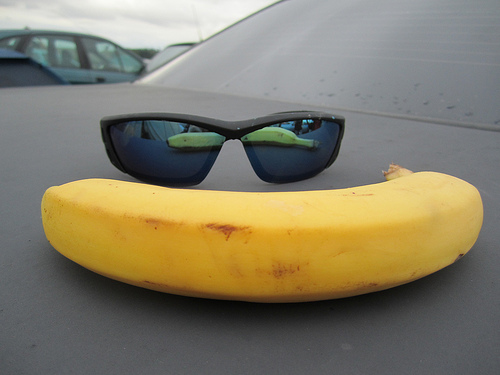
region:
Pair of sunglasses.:
[99, 85, 375, 182]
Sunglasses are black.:
[67, 95, 375, 182]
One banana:
[39, 151, 469, 373]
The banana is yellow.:
[44, 177, 487, 308]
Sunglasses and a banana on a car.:
[47, 92, 484, 313]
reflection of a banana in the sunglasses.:
[165, 122, 333, 152]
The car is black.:
[22, 77, 478, 365]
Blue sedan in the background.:
[2, 18, 153, 95]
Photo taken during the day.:
[27, 2, 496, 369]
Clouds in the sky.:
[6, 3, 264, 54]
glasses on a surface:
[98, 66, 363, 185]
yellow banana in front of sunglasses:
[57, 161, 474, 320]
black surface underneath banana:
[264, 304, 375, 350]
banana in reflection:
[273, 122, 313, 160]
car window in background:
[71, 21, 140, 75]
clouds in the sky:
[141, 9, 186, 38]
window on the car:
[30, 34, 76, 78]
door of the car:
[91, 78, 113, 88]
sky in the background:
[139, 11, 196, 32]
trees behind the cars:
[138, 38, 159, 63]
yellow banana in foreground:
[37, 161, 489, 308]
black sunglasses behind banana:
[91, 90, 348, 190]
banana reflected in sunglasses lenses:
[170, 111, 323, 162]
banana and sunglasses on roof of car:
[34, 104, 489, 310]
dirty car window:
[148, 1, 498, 126]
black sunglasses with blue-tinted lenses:
[93, 100, 355, 185]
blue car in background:
[1, 27, 156, 88]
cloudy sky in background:
[1, 0, 281, 45]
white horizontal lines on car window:
[187, 0, 498, 122]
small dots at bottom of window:
[175, 62, 498, 135]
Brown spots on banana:
[197, 208, 314, 285]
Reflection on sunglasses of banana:
[143, 90, 316, 160]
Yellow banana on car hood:
[18, 141, 493, 312]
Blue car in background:
[7, 18, 140, 93]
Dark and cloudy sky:
[2, 0, 261, 73]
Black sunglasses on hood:
[92, 87, 340, 204]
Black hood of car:
[4, 75, 489, 372]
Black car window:
[138, 6, 493, 130]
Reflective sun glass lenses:
[95, 117, 351, 183]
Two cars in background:
[1, 15, 158, 105]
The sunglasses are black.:
[95, 95, 387, 203]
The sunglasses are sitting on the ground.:
[46, 83, 398, 190]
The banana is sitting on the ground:
[32, 162, 494, 330]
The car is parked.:
[13, 15, 177, 85]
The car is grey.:
[7, 21, 171, 93]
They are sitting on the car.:
[15, 35, 485, 349]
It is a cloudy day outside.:
[69, 9, 197, 36]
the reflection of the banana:
[105, 99, 337, 183]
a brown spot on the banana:
[135, 202, 275, 242]